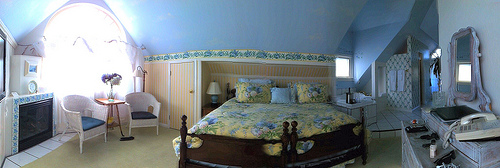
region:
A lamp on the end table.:
[206, 81, 226, 106]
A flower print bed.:
[175, 75, 367, 166]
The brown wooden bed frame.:
[179, 109, 373, 166]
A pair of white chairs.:
[52, 87, 166, 155]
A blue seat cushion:
[77, 114, 107, 130]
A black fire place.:
[14, 99, 58, 151]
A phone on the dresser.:
[440, 112, 499, 142]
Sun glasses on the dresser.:
[429, 147, 457, 167]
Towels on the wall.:
[387, 64, 407, 97]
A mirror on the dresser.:
[433, 21, 498, 116]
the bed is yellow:
[169, 74, 320, 155]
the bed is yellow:
[163, 15, 373, 140]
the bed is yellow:
[199, 50, 414, 157]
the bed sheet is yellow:
[193, 87, 333, 149]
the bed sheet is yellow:
[239, 91, 321, 162]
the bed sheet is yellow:
[223, 97, 283, 151]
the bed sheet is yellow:
[237, 108, 279, 145]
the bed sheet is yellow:
[247, 88, 294, 143]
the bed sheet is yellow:
[199, 68, 273, 146]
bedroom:
[0, 7, 495, 160]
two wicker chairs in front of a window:
[58, 79, 168, 153]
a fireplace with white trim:
[8, 86, 65, 162]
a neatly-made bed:
[176, 70, 372, 166]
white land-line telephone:
[446, 107, 498, 146]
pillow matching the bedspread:
[234, 78, 273, 107]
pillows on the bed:
[235, 71, 338, 107]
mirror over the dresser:
[450, 27, 486, 107]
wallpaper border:
[127, 45, 344, 65]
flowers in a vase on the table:
[100, 70, 126, 106]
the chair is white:
[56, 92, 127, 156]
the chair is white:
[9, 61, 179, 165]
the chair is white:
[33, 71, 135, 148]